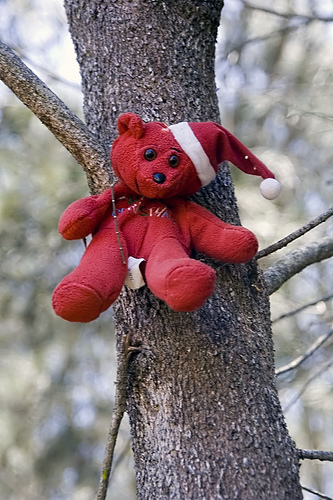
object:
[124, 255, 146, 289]
tag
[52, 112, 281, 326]
bear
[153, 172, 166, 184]
nose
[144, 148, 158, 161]
eye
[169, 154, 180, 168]
eye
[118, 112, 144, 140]
ear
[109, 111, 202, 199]
head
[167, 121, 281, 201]
hat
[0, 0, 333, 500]
tree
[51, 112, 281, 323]
doll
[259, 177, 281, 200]
puff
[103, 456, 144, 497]
snow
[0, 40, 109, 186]
branch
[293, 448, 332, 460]
branch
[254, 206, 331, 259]
branch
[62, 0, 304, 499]
trunk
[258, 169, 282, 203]
tip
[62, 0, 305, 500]
bark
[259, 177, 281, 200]
ball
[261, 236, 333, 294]
branches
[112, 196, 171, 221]
writing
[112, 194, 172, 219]
chest